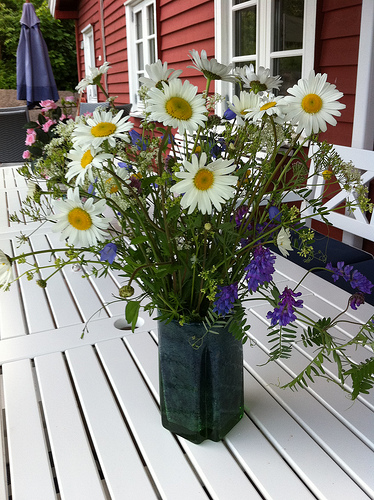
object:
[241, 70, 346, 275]
daisies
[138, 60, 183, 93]
flowers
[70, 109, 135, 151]
flower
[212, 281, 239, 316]
flower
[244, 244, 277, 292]
flower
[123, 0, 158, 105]
window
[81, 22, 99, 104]
window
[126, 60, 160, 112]
trim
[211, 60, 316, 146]
trim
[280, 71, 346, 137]
flower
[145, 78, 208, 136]
flower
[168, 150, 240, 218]
daisy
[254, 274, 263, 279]
petals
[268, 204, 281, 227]
flower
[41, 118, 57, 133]
flowers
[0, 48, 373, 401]
bouquet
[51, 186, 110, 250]
flowers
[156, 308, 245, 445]
vase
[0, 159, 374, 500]
table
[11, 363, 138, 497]
planks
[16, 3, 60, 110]
umbrella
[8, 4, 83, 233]
side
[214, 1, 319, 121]
window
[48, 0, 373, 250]
building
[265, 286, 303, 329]
flower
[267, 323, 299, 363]
leaf